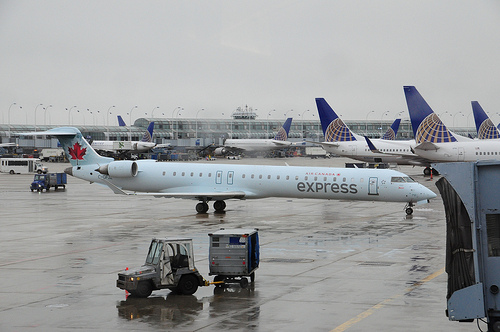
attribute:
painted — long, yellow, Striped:
[316, 261, 450, 328]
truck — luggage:
[114, 221, 268, 301]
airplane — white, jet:
[29, 122, 441, 224]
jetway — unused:
[416, 154, 482, 324]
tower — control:
[221, 100, 265, 120]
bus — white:
[4, 131, 34, 180]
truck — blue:
[29, 167, 71, 196]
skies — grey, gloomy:
[75, 28, 324, 98]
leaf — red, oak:
[59, 140, 89, 166]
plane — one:
[26, 118, 114, 185]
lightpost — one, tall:
[23, 88, 55, 134]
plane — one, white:
[24, 117, 440, 221]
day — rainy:
[1, 1, 484, 329]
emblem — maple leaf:
[65, 142, 88, 166]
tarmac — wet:
[1, 153, 484, 330]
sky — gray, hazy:
[1, 0, 483, 127]